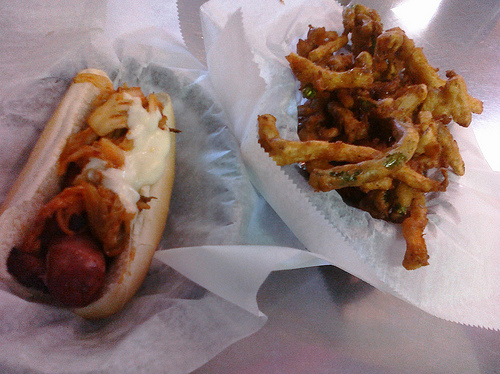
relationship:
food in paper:
[287, 19, 454, 200] [282, 185, 330, 250]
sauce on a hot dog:
[135, 138, 152, 170] [41, 69, 151, 294]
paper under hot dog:
[282, 185, 330, 250] [41, 69, 151, 294]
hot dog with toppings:
[41, 69, 151, 294] [82, 123, 118, 218]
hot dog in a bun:
[41, 69, 151, 294] [61, 94, 84, 134]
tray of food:
[189, 118, 245, 262] [287, 19, 454, 200]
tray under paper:
[189, 118, 245, 262] [282, 185, 330, 250]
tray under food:
[189, 118, 245, 262] [287, 19, 454, 200]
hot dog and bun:
[41, 69, 151, 294] [61, 94, 84, 134]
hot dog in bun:
[41, 69, 151, 294] [61, 94, 84, 134]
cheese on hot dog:
[131, 134, 149, 167] [41, 69, 151, 294]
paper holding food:
[282, 185, 330, 250] [287, 19, 454, 200]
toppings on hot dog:
[82, 123, 118, 218] [41, 69, 151, 294]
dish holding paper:
[189, 118, 245, 262] [282, 185, 330, 250]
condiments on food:
[96, 116, 115, 218] [98, 97, 135, 123]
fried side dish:
[357, 66, 426, 161] [297, 191, 350, 235]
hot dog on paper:
[41, 69, 151, 294] [282, 185, 330, 250]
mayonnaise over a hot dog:
[138, 133, 158, 190] [41, 69, 151, 294]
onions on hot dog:
[65, 194, 113, 242] [41, 69, 151, 294]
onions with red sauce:
[65, 194, 113, 242] [29, 205, 121, 233]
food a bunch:
[278, 19, 454, 200] [314, 35, 420, 97]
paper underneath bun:
[282, 185, 330, 250] [61, 94, 84, 134]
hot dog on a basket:
[41, 69, 151, 294] [189, 118, 245, 262]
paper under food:
[282, 185, 330, 250] [287, 19, 454, 200]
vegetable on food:
[331, 74, 393, 147] [278, 19, 454, 200]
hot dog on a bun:
[41, 69, 151, 294] [61, 94, 84, 134]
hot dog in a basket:
[41, 69, 151, 294] [246, 148, 303, 202]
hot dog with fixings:
[41, 69, 151, 294] [80, 170, 116, 237]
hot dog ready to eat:
[41, 69, 151, 294] [70, 88, 159, 121]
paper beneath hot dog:
[282, 185, 330, 250] [41, 69, 151, 294]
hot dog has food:
[41, 69, 151, 294] [88, 91, 135, 133]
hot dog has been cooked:
[41, 69, 151, 294] [52, 239, 98, 288]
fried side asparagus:
[357, 66, 426, 161] [345, 18, 423, 93]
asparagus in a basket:
[345, 18, 423, 93] [246, 148, 303, 202]